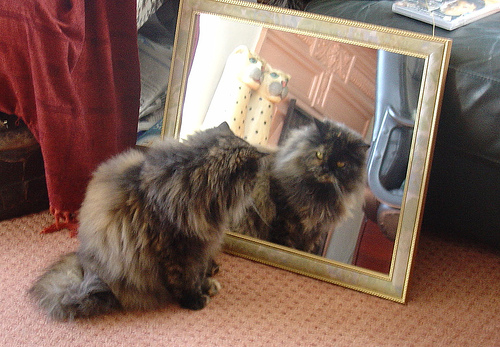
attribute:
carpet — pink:
[1, 214, 500, 346]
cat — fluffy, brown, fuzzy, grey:
[20, 118, 280, 328]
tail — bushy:
[20, 253, 127, 325]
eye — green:
[311, 148, 328, 164]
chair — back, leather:
[360, 49, 428, 211]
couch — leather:
[295, 2, 498, 266]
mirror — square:
[175, 15, 425, 281]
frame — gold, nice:
[161, 1, 455, 309]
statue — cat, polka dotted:
[200, 41, 267, 141]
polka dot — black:
[242, 93, 250, 103]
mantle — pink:
[253, 23, 378, 271]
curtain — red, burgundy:
[2, 3, 146, 240]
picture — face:
[389, 2, 499, 36]